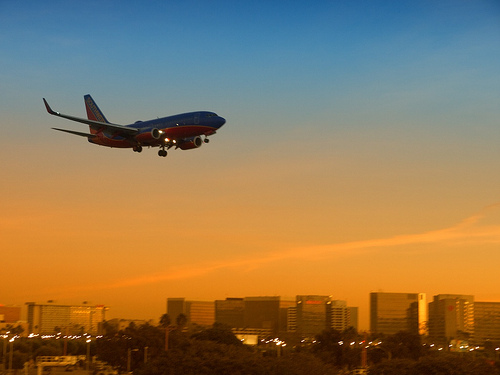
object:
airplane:
[42, 80, 230, 162]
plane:
[86, 97, 223, 151]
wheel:
[160, 134, 211, 169]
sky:
[1, 1, 498, 328]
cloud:
[11, 204, 499, 298]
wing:
[56, 102, 97, 132]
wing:
[61, 127, 86, 142]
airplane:
[37, 76, 239, 165]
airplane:
[42, 76, 227, 171]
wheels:
[133, 137, 175, 167]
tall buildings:
[25, 292, 498, 347]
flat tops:
[26, 293, 498, 308]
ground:
[456, 137, 461, 162]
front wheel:
[202, 134, 209, 146]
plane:
[36, 88, 228, 160]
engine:
[174, 131, 207, 154]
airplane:
[36, 89, 231, 163]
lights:
[0, 325, 500, 355]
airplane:
[29, 70, 241, 172]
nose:
[212, 105, 228, 130]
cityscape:
[5, 282, 498, 354]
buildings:
[8, 292, 498, 341]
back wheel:
[131, 141, 146, 154]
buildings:
[24, 238, 499, 369]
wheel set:
[202, 138, 212, 145]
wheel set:
[154, 148, 170, 157]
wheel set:
[131, 143, 148, 153]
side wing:
[51, 125, 95, 138]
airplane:
[41, 90, 228, 159]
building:
[426, 293, 498, 346]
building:
[369, 292, 418, 335]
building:
[166, 294, 356, 334]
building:
[23, 300, 105, 336]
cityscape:
[3, 290, 498, 352]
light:
[162, 135, 172, 145]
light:
[168, 137, 178, 145]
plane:
[40, 93, 227, 158]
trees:
[94, 316, 254, 365]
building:
[245, 274, 370, 355]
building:
[224, 262, 460, 374]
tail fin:
[43, 88, 112, 143]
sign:
[305, 298, 323, 306]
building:
[295, 291, 330, 345]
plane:
[30, 75, 235, 176]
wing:
[39, 96, 139, 136]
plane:
[41, 83, 228, 158]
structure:
[36, 354, 90, 371]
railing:
[33, 354, 81, 364]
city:
[2, 293, 499, 369]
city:
[1, 283, 499, 372]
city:
[3, 290, 498, 362]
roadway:
[2, 338, 497, 355]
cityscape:
[1, 287, 499, 343]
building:
[293, 277, 381, 349]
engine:
[139, 121, 184, 158]